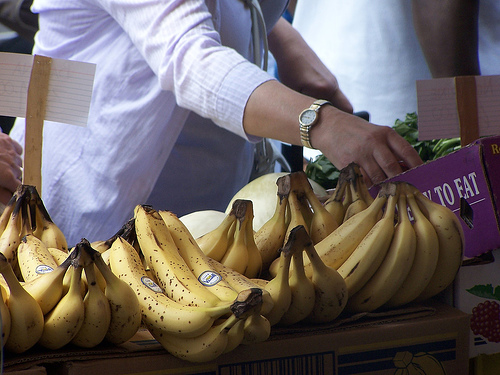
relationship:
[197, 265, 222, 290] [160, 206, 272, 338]
sticker on a banana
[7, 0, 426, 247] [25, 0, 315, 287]
man wearing a shirt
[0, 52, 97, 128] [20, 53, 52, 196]
sign on a stick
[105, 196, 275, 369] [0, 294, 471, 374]
bananas in a box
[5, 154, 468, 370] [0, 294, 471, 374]
bananas in a box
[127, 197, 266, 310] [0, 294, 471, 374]
banana in a box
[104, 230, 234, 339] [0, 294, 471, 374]
banana in a box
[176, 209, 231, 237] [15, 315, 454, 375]
melon on a table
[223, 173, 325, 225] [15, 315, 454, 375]
melon on a table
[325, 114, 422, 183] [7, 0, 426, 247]
hand of a man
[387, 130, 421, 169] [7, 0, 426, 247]
index finger of a man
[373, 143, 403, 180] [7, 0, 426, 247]
middle finger of a man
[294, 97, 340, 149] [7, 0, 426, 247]
man's wrist of man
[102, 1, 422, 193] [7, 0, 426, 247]
arm of man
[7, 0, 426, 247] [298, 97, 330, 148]
man wearing watch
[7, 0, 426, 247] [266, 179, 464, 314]
man near bananas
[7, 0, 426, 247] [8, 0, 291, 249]
man wearing shirt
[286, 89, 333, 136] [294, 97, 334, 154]
watch on man's wrist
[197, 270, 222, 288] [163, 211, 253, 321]
sticker on banana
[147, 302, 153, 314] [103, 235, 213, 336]
spot on banana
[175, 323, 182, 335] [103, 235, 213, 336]
spot on banana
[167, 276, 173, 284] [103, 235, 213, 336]
spot on banana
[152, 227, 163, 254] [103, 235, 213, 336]
spot on banana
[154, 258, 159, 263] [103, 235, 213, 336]
spot on banana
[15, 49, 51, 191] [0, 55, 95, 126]
stick attached to sign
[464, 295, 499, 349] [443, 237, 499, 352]
berries printed on box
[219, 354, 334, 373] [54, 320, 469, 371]
barcode on box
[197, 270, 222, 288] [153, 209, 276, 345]
sticker on banana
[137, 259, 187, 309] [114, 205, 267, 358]
spots on banana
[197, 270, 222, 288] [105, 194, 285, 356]
sticker on bananas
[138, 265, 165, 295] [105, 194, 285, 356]
sticker on bananas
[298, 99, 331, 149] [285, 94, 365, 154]
watch on wrist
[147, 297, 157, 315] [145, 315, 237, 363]
mark on banana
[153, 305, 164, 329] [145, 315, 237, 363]
mark on banana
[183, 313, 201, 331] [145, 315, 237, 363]
mark on banana